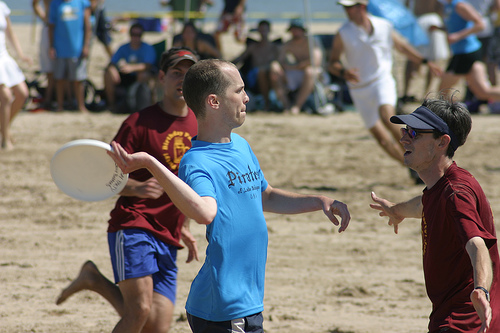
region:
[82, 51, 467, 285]
people playing some frisbee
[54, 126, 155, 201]
a white toy frisbee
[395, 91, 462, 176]
the head of an adult man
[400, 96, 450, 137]
the visor of a grown man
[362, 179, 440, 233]
the arm of a grown man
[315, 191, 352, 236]
the hand of a grown man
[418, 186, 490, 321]
the red shirt of a man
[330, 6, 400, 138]
a person running on the beach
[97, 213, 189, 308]
a pair of blue swim shorts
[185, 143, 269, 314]
a bright blue short sleeve shirt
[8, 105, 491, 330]
Light brown sand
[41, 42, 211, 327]
A person running barefooted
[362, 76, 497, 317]
A man with his arms outwards to the sides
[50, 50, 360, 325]
A man holding a frisbee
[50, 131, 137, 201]
A round white frisbee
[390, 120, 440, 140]
A pair of sunglasses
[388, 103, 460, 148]
A dark blue sunvisor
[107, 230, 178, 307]
A pair of blue sports shorts with white stripes on the sides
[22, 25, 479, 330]
People playing with a frisbee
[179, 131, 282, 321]
A light blue short sleeved shirt with writing on the front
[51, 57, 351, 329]
man is throwing a frisbee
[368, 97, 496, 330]
man is wearing a black visor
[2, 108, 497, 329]
sand is on the beach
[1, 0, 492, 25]
body of water in the background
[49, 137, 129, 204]
round white frisbee in man's hand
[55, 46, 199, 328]
man is running on the beach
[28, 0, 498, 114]
spectators are watching in the background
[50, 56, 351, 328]
man has a frisbee in his right hand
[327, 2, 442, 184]
man in white is running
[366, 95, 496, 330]
man is holding his arms out to block frisbee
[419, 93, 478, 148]
The man has dark hair.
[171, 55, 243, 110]
The man has dark hair.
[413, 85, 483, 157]
The mans hair is brown.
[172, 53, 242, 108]
The mans hair is brown.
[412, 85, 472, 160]
The mans hair is short.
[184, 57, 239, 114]
The mans hair is short.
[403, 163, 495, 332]
The man is wearing a red shirt.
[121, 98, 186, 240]
The man is wearing a red shirt.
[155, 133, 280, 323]
The man is wearing a blue shirt.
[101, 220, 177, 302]
The man is wearing blue shorts.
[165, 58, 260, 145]
head of a person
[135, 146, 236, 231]
arm of a person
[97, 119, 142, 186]
hand of a person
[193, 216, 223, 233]
elbow of a person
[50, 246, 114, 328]
feet of a person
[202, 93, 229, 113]
ear of a person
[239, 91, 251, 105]
nose of a person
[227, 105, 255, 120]
mouth of a person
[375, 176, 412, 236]
hand of a person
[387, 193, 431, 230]
arm of a person